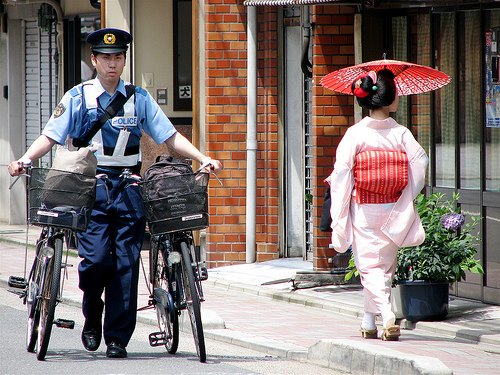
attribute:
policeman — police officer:
[13, 24, 225, 179]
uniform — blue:
[11, 75, 227, 305]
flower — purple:
[438, 208, 470, 239]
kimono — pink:
[325, 118, 432, 302]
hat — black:
[86, 24, 135, 56]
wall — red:
[210, 7, 248, 52]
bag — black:
[141, 149, 193, 177]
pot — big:
[403, 266, 457, 325]